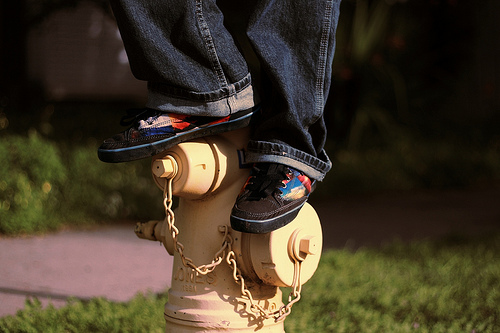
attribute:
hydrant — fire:
[133, 146, 294, 325]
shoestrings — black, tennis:
[231, 164, 321, 233]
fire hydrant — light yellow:
[125, 120, 333, 332]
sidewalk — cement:
[0, 180, 497, 325]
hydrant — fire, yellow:
[128, 109, 327, 331]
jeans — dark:
[178, 42, 450, 123]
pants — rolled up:
[134, 47, 337, 182]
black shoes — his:
[117, 78, 315, 211]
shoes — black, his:
[125, 112, 308, 229]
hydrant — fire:
[160, 140, 318, 331]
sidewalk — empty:
[2, 234, 131, 304]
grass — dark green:
[14, 114, 488, 329]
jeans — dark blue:
[104, 0, 344, 220]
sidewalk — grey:
[47, 242, 175, 302]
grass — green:
[17, 235, 497, 331]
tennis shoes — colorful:
[93, 102, 323, 233]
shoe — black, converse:
[225, 160, 317, 236]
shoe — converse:
[89, 102, 261, 165]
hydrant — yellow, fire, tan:
[139, 123, 316, 328]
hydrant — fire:
[127, 157, 303, 332]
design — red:
[138, 111, 198, 131]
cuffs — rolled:
[145, 75, 256, 117]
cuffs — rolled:
[238, 139, 333, 182]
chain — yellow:
[164, 187, 306, 322]